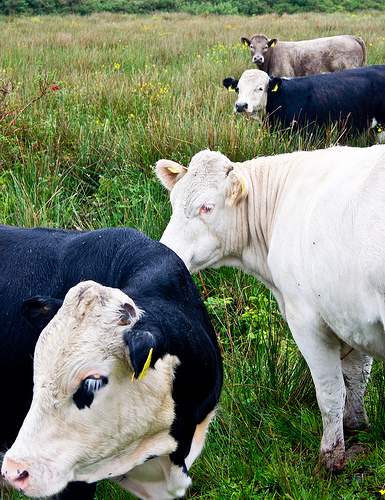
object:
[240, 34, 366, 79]
cow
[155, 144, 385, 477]
cow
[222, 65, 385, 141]
cow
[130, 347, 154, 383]
tag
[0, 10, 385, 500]
grass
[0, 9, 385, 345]
flower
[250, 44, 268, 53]
eye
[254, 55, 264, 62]
nose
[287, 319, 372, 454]
legs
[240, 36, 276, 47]
ear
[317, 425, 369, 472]
feet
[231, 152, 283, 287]
neck